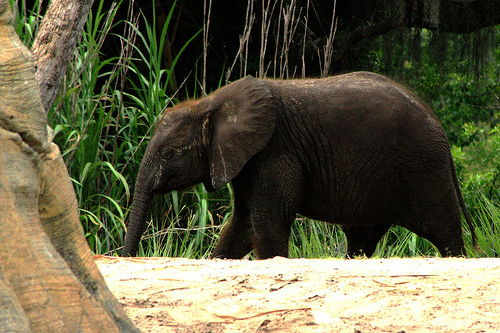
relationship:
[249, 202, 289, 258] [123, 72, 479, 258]
leg on elephant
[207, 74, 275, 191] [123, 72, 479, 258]
ear on elephant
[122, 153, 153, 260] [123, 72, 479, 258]
trunk on elephant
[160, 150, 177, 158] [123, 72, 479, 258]
eye on elephant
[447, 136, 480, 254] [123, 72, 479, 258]
tail on elephant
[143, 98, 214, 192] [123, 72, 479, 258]
head on elephant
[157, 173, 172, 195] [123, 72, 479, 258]
mouth on elephant